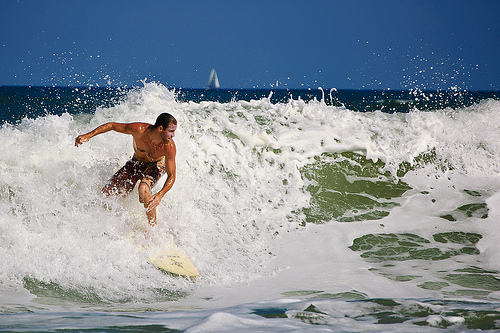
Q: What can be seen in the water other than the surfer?
A: Boat.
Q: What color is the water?
A: Green.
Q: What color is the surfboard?
A: Tan.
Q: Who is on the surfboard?
A: The man.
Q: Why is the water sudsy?
A: Waves.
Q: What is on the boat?
A: Sail.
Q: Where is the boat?
A: Behind the man.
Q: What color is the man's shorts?
A: Tan and black.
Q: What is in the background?
A: A clear blue sky above ocean.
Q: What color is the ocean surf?
A: Green and white.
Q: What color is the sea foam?
A: White.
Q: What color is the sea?
A: Green.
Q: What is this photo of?
A: A young man surfing in ocean.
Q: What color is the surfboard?
A: Tan.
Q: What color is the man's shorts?
A: Dark brown.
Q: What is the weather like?
A: Sunny.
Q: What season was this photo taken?
A: Summer.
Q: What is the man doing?
A: Surfing.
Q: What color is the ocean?
A: Green and white.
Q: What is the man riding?
A: A wave.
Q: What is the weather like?
A: Sunny.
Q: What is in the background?
A: Blue sky.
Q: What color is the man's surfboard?
A: Beige.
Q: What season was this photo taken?
A: Summer.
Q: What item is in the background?
A: A sailboat.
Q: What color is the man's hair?
A: Dark brown.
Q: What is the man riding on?
A: Surfboard.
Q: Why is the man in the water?
A: Surfing.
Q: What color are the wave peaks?
A: White.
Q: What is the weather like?
A: Clear.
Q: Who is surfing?
A: A man.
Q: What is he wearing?
A: Shorts.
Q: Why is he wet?
A: He is in the water.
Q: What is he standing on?
A: A surfboard.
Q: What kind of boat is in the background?
A: Sailboat.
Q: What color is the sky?
A: Blue.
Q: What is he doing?
A: Surfing.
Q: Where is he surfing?
A: In the water.